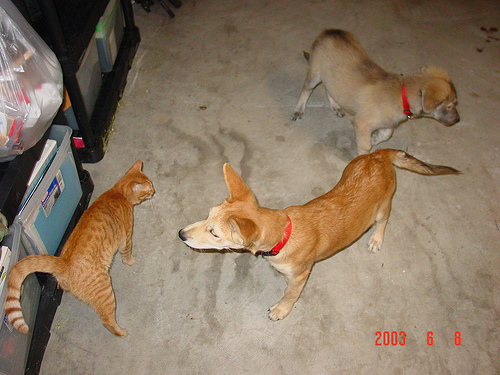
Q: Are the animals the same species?
A: No, they are dogs and cats.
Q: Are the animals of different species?
A: Yes, they are dogs and cats.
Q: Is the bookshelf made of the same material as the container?
A: Yes, both the bookshelf and the container are made of plastic.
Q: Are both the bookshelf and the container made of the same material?
A: Yes, both the bookshelf and the container are made of plastic.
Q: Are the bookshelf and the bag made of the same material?
A: Yes, both the bookshelf and the bag are made of plastic.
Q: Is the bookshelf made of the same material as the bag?
A: Yes, both the bookshelf and the bag are made of plastic.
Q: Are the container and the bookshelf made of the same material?
A: Yes, both the container and the bookshelf are made of plastic.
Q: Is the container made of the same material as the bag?
A: Yes, both the container and the bag are made of plastic.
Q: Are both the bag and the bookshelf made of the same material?
A: Yes, both the bag and the bookshelf are made of plastic.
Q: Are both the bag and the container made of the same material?
A: Yes, both the bag and the container are made of plastic.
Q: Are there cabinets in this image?
A: No, there are no cabinets.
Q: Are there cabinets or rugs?
A: No, there are no cabinets or rugs.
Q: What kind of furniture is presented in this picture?
A: The furniture is a bookshelf.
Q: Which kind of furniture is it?
A: The piece of furniture is a bookshelf.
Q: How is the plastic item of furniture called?
A: The piece of furniture is a bookshelf.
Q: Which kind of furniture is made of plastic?
A: The furniture is a bookshelf.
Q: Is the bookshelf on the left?
A: Yes, the bookshelf is on the left of the image.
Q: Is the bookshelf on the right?
A: No, the bookshelf is on the left of the image.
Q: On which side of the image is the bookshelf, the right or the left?
A: The bookshelf is on the left of the image.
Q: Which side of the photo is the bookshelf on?
A: The bookshelf is on the left of the image.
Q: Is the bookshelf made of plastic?
A: Yes, the bookshelf is made of plastic.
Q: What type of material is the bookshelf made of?
A: The bookshelf is made of plastic.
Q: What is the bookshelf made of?
A: The bookshelf is made of plastic.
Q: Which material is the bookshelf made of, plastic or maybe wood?
A: The bookshelf is made of plastic.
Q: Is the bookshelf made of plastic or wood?
A: The bookshelf is made of plastic.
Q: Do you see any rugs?
A: No, there are no rugs.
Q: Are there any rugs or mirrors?
A: No, there are no rugs or mirrors.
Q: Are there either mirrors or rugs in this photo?
A: No, there are no rugs or mirrors.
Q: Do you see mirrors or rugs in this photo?
A: No, there are no rugs or mirrors.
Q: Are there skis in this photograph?
A: No, there are no skis.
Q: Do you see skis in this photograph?
A: No, there are no skis.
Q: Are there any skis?
A: No, there are no skis.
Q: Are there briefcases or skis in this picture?
A: No, there are no skis or briefcases.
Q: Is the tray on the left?
A: Yes, the tray is on the left of the image.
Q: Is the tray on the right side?
A: No, the tray is on the left of the image.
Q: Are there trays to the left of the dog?
A: Yes, there is a tray to the left of the dog.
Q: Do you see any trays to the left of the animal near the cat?
A: Yes, there is a tray to the left of the dog.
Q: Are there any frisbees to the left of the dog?
A: No, there is a tray to the left of the dog.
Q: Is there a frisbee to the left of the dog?
A: No, there is a tray to the left of the dog.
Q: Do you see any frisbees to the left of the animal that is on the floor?
A: No, there is a tray to the left of the dog.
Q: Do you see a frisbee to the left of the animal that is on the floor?
A: No, there is a tray to the left of the dog.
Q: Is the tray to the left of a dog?
A: Yes, the tray is to the left of a dog.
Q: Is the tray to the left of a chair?
A: No, the tray is to the left of a dog.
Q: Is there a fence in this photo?
A: No, there are no fences.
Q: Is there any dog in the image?
A: Yes, there is a dog.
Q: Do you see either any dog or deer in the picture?
A: Yes, there is a dog.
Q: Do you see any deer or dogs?
A: Yes, there is a dog.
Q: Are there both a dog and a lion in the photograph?
A: No, there is a dog but no lions.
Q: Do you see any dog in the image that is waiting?
A: Yes, there is a dog that is waiting.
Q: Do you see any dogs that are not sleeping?
A: Yes, there is a dog that is waiting .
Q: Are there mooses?
A: No, there are no mooses.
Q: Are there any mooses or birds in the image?
A: No, there are no mooses or birds.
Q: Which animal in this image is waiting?
A: The animal is a dog.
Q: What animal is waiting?
A: The animal is a dog.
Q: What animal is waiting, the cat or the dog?
A: The dog is waiting.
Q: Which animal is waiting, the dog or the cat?
A: The dog is waiting.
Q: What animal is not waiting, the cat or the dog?
A: The cat is not waiting.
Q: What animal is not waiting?
A: The animal is a cat.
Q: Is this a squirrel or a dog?
A: This is a dog.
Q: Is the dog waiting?
A: Yes, the dog is waiting.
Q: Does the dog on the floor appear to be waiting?
A: Yes, the dog is waiting.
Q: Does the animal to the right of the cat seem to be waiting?
A: Yes, the dog is waiting.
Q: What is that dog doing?
A: The dog is waiting.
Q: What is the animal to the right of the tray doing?
A: The dog is waiting.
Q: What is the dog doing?
A: The dog is waiting.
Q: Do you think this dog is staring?
A: No, the dog is waiting.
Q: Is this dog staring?
A: No, the dog is waiting.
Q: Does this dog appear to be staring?
A: No, the dog is waiting.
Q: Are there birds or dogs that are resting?
A: No, there is a dog but it is waiting.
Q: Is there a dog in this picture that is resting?
A: No, there is a dog but it is waiting.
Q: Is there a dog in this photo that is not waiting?
A: No, there is a dog but it is waiting.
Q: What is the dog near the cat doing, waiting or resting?
A: The dog is waiting.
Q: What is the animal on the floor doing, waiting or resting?
A: The dog is waiting.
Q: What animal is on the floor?
A: The dog is on the floor.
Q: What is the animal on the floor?
A: The animal is a dog.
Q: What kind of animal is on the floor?
A: The animal is a dog.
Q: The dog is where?
A: The dog is on the floor.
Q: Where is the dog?
A: The dog is on the floor.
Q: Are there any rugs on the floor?
A: No, there is a dog on the floor.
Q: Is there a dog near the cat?
A: Yes, there is a dog near the cat.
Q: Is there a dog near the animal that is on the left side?
A: Yes, there is a dog near the cat.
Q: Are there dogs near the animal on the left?
A: Yes, there is a dog near the cat.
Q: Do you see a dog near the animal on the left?
A: Yes, there is a dog near the cat.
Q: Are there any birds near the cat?
A: No, there is a dog near the cat.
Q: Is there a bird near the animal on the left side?
A: No, there is a dog near the cat.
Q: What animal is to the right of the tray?
A: The animal is a dog.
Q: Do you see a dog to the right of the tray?
A: Yes, there is a dog to the right of the tray.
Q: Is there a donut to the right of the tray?
A: No, there is a dog to the right of the tray.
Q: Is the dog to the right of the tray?
A: Yes, the dog is to the right of the tray.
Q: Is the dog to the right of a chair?
A: No, the dog is to the right of the tray.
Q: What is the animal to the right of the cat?
A: The animal is a dog.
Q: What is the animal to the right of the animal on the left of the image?
A: The animal is a dog.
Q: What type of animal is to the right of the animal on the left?
A: The animal is a dog.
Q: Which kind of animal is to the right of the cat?
A: The animal is a dog.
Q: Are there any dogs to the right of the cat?
A: Yes, there is a dog to the right of the cat.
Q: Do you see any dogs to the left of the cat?
A: No, the dog is to the right of the cat.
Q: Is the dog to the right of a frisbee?
A: No, the dog is to the right of the cat.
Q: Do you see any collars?
A: Yes, there is a collar.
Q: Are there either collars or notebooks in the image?
A: Yes, there is a collar.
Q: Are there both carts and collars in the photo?
A: No, there is a collar but no carts.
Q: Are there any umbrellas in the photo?
A: No, there are no umbrellas.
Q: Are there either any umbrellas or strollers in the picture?
A: No, there are no umbrellas or strollers.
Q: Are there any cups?
A: No, there are no cups.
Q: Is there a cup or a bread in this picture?
A: No, there are no cups or breads.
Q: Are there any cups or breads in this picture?
A: No, there are no cups or breads.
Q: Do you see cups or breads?
A: No, there are no cups or breads.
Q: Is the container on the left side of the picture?
A: Yes, the container is on the left of the image.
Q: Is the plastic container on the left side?
A: Yes, the container is on the left of the image.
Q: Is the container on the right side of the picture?
A: No, the container is on the left of the image.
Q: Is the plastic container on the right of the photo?
A: No, the container is on the left of the image.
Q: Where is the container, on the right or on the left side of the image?
A: The container is on the left of the image.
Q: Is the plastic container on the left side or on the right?
A: The container is on the left of the image.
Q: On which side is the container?
A: The container is on the left of the image.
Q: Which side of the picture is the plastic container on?
A: The container is on the left of the image.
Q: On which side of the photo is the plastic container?
A: The container is on the left of the image.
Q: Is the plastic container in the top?
A: Yes, the container is in the top of the image.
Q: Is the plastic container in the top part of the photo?
A: Yes, the container is in the top of the image.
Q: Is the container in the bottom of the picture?
A: No, the container is in the top of the image.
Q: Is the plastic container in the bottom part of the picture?
A: No, the container is in the top of the image.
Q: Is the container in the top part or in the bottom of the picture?
A: The container is in the top of the image.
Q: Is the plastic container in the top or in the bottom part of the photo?
A: The container is in the top of the image.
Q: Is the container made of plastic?
A: Yes, the container is made of plastic.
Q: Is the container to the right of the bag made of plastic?
A: Yes, the container is made of plastic.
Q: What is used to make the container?
A: The container is made of plastic.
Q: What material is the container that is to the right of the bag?
A: The container is made of plastic.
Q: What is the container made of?
A: The container is made of plastic.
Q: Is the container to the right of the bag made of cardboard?
A: No, the container is made of plastic.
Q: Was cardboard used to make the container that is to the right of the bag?
A: No, the container is made of plastic.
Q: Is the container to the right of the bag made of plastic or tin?
A: The container is made of plastic.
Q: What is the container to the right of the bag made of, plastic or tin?
A: The container is made of plastic.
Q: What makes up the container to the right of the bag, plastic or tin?
A: The container is made of plastic.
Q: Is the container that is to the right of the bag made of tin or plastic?
A: The container is made of plastic.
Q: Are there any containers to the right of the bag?
A: Yes, there is a container to the right of the bag.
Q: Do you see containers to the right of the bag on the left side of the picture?
A: Yes, there is a container to the right of the bag.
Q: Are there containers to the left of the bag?
A: No, the container is to the right of the bag.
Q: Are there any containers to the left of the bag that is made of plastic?
A: No, the container is to the right of the bag.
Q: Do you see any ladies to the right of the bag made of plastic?
A: No, there is a container to the right of the bag.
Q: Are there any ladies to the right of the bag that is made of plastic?
A: No, there is a container to the right of the bag.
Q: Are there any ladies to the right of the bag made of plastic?
A: No, there is a container to the right of the bag.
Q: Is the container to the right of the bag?
A: Yes, the container is to the right of the bag.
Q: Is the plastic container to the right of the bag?
A: Yes, the container is to the right of the bag.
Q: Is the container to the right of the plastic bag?
A: Yes, the container is to the right of the bag.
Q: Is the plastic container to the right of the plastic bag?
A: Yes, the container is to the right of the bag.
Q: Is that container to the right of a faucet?
A: No, the container is to the right of the bag.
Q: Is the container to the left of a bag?
A: No, the container is to the right of a bag.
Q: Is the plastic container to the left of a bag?
A: No, the container is to the right of a bag.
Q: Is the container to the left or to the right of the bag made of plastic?
A: The container is to the right of the bag.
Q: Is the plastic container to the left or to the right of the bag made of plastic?
A: The container is to the right of the bag.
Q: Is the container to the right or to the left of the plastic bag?
A: The container is to the right of the bag.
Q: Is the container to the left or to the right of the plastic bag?
A: The container is to the right of the bag.